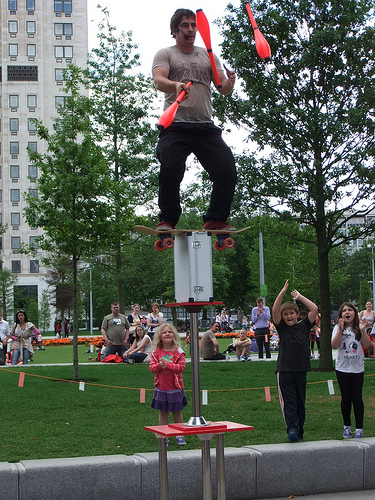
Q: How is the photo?
A: Clear.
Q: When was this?
A: Daytime.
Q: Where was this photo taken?
A: In a park.